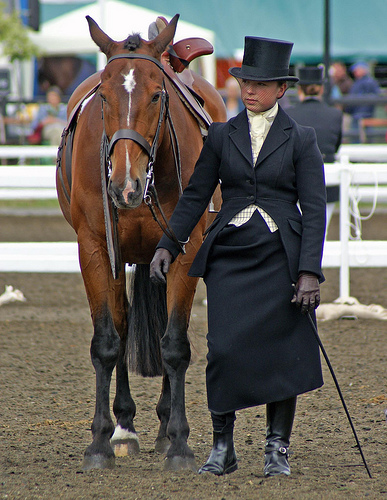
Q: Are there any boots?
A: Yes, there are boots.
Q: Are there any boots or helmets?
A: Yes, there are boots.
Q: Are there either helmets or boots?
A: Yes, there are boots.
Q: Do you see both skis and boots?
A: No, there are boots but no skis.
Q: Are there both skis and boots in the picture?
A: No, there are boots but no skis.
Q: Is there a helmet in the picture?
A: No, there are no helmets.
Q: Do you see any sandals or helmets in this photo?
A: No, there are no helmets or sandals.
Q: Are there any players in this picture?
A: No, there are no players.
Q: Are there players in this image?
A: No, there are no players.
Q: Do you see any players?
A: No, there are no players.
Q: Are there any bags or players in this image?
A: No, there are no players or bags.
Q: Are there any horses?
A: Yes, there is a horse.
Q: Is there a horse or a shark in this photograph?
A: Yes, there is a horse.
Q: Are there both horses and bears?
A: No, there is a horse but no bears.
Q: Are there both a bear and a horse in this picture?
A: No, there is a horse but no bears.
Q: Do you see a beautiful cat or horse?
A: Yes, there is a beautiful horse.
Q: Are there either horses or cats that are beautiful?
A: Yes, the horse is beautiful.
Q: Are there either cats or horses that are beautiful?
A: Yes, the horse is beautiful.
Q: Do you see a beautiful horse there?
A: Yes, there is a beautiful horse.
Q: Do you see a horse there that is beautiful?
A: Yes, there is a horse that is beautiful.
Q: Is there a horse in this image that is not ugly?
A: Yes, there is an beautiful horse.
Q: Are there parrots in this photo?
A: No, there are no parrots.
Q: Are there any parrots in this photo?
A: No, there are no parrots.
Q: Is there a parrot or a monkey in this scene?
A: No, there are no parrots or monkeys.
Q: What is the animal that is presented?
A: The animal is a horse.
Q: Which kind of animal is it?
A: The animal is a horse.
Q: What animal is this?
A: This is a horse.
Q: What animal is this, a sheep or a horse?
A: This is a horse.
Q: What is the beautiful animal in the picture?
A: The animal is a horse.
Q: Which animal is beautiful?
A: The animal is a horse.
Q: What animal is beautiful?
A: The animal is a horse.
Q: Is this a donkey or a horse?
A: This is a horse.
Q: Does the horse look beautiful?
A: Yes, the horse is beautiful.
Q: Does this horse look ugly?
A: No, the horse is beautiful.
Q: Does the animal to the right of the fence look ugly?
A: No, the horse is beautiful.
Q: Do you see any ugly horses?
A: No, there is a horse but it is beautiful.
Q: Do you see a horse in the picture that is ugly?
A: No, there is a horse but it is beautiful.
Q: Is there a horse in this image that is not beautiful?
A: No, there is a horse but it is beautiful.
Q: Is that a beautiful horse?
A: Yes, that is a beautiful horse.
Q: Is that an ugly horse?
A: No, that is a beautiful horse.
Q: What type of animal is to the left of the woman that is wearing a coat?
A: The animal is a horse.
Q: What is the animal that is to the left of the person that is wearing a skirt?
A: The animal is a horse.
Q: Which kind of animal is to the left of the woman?
A: The animal is a horse.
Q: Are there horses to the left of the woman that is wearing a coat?
A: Yes, there is a horse to the left of the woman.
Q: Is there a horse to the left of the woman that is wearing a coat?
A: Yes, there is a horse to the left of the woman.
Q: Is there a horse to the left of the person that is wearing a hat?
A: Yes, there is a horse to the left of the woman.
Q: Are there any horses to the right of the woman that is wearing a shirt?
A: No, the horse is to the left of the woman.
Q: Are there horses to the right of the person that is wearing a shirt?
A: No, the horse is to the left of the woman.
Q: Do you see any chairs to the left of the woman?
A: No, there is a horse to the left of the woman.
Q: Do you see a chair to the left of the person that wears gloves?
A: No, there is a horse to the left of the woman.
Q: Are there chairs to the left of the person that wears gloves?
A: No, there is a horse to the left of the woman.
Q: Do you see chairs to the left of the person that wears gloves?
A: No, there is a horse to the left of the woman.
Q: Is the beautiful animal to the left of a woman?
A: Yes, the horse is to the left of a woman.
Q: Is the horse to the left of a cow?
A: No, the horse is to the left of a woman.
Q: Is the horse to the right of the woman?
A: No, the horse is to the left of the woman.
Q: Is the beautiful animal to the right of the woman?
A: No, the horse is to the left of the woman.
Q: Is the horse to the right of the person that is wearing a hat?
A: No, the horse is to the left of the woman.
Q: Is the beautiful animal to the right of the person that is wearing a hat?
A: No, the horse is to the left of the woman.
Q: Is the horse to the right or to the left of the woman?
A: The horse is to the left of the woman.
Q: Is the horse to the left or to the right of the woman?
A: The horse is to the left of the woman.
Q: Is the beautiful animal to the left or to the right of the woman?
A: The horse is to the left of the woman.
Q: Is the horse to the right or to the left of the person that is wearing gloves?
A: The horse is to the left of the woman.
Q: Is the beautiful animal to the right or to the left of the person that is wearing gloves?
A: The horse is to the left of the woman.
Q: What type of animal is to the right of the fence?
A: The animal is a horse.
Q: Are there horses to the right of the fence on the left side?
A: Yes, there is a horse to the right of the fence.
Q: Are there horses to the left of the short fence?
A: No, the horse is to the right of the fence.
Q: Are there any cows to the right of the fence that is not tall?
A: No, there is a horse to the right of the fence.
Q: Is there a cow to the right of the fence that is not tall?
A: No, there is a horse to the right of the fence.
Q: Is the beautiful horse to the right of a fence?
A: Yes, the horse is to the right of a fence.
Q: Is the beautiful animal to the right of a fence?
A: Yes, the horse is to the right of a fence.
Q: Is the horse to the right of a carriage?
A: No, the horse is to the right of a fence.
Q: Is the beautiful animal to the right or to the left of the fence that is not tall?
A: The horse is to the right of the fence.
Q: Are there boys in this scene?
A: No, there are no boys.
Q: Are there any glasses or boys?
A: No, there are no boys or glasses.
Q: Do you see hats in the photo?
A: Yes, there is a hat.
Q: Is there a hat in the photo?
A: Yes, there is a hat.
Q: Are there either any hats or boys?
A: Yes, there is a hat.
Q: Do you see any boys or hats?
A: Yes, there is a hat.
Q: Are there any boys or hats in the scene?
A: Yes, there is a hat.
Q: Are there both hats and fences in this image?
A: Yes, there are both a hat and a fence.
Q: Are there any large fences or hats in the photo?
A: Yes, there is a large hat.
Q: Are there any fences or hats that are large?
A: Yes, the hat is large.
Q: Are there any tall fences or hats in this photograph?
A: Yes, there is a tall hat.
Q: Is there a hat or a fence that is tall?
A: Yes, the hat is tall.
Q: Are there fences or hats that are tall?
A: Yes, the hat is tall.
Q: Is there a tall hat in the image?
A: Yes, there is a tall hat.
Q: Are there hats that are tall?
A: Yes, there is a hat that is tall.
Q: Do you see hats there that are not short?
A: Yes, there is a tall hat.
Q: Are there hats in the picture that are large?
A: Yes, there is a large hat.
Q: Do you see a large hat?
A: Yes, there is a large hat.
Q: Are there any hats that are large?
A: Yes, there is a hat that is large.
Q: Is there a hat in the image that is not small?
A: Yes, there is a large hat.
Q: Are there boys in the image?
A: No, there are no boys.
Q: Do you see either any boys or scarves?
A: No, there are no boys or scarves.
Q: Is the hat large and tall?
A: Yes, the hat is large and tall.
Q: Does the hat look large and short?
A: No, the hat is large but tall.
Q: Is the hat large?
A: Yes, the hat is large.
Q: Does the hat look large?
A: Yes, the hat is large.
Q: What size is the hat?
A: The hat is large.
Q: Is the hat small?
A: No, the hat is large.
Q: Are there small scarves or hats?
A: No, there is a hat but it is large.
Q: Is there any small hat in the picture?
A: No, there is a hat but it is large.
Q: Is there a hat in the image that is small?
A: No, there is a hat but it is large.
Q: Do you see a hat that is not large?
A: No, there is a hat but it is large.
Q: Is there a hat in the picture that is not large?
A: No, there is a hat but it is large.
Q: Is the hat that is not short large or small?
A: The hat is large.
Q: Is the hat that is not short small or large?
A: The hat is large.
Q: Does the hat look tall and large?
A: Yes, the hat is tall and large.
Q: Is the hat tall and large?
A: Yes, the hat is tall and large.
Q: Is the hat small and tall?
A: No, the hat is tall but large.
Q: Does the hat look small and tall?
A: No, the hat is tall but large.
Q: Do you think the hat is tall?
A: Yes, the hat is tall.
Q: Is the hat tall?
A: Yes, the hat is tall.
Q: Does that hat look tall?
A: Yes, the hat is tall.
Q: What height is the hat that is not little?
A: The hat is tall.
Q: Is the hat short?
A: No, the hat is tall.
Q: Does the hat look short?
A: No, the hat is tall.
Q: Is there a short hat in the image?
A: No, there is a hat but it is tall.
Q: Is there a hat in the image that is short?
A: No, there is a hat but it is tall.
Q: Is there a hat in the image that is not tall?
A: No, there is a hat but it is tall.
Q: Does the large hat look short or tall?
A: The hat is tall.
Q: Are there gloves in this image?
A: Yes, there are gloves.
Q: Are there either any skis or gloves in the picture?
A: Yes, there are gloves.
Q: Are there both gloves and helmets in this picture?
A: No, there are gloves but no helmets.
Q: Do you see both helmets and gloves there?
A: No, there are gloves but no helmets.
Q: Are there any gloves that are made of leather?
A: Yes, there are gloves that are made of leather.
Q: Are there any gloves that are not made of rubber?
A: Yes, there are gloves that are made of leather.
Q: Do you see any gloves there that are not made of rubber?
A: Yes, there are gloves that are made of leather.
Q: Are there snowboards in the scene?
A: No, there are no snowboards.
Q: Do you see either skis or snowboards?
A: No, there are no snowboards or skis.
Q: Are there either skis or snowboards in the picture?
A: No, there are no snowboards or skis.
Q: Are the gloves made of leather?
A: Yes, the gloves are made of leather.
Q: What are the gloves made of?
A: The gloves are made of leather.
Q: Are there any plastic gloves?
A: No, there are gloves but they are made of leather.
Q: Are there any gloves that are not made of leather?
A: No, there are gloves but they are made of leather.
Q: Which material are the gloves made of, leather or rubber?
A: The gloves are made of leather.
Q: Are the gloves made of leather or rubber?
A: The gloves are made of leather.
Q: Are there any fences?
A: Yes, there is a fence.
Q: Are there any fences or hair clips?
A: Yes, there is a fence.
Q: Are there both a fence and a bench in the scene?
A: No, there is a fence but no benches.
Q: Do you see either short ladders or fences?
A: Yes, there is a short fence.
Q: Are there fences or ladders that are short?
A: Yes, the fence is short.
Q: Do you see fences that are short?
A: Yes, there is a short fence.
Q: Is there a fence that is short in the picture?
A: Yes, there is a short fence.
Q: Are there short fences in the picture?
A: Yes, there is a short fence.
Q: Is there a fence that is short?
A: Yes, there is a fence that is short.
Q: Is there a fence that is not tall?
A: Yes, there is a short fence.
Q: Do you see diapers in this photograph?
A: No, there are no diapers.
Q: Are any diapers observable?
A: No, there are no diapers.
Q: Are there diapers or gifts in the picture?
A: No, there are no diapers or gifts.